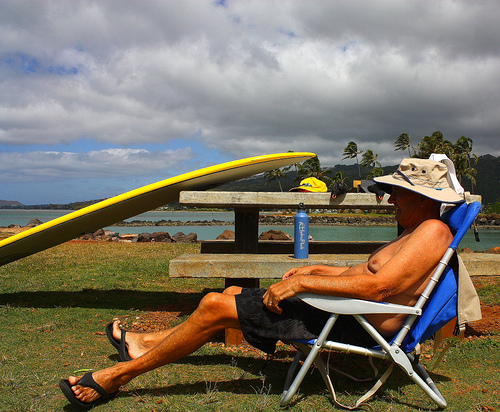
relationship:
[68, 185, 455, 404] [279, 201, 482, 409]
man relaxing in lawn chair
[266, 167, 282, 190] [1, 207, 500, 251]
palm tree on other side of river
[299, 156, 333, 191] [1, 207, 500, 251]
palm tree on other side of river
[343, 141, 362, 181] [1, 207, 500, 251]
palm tree on other side of river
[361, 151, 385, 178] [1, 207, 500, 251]
palm tree on other side of river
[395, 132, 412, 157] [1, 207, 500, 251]
palm tree on other side of river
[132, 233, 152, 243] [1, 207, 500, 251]
rock on bank of river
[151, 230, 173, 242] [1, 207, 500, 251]
rock on bank of river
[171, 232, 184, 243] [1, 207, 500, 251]
rock on bank of river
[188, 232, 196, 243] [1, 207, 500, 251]
rock on bank of river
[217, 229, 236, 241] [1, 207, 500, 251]
rock on bank of river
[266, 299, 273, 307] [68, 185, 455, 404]
wedding ring of man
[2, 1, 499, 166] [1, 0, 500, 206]
clouds in sky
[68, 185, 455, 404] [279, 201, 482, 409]
man sitting in lawn chair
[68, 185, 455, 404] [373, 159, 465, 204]
man with hat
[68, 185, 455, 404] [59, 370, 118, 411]
man wearing flip flop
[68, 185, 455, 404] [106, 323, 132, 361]
man wearing flip flop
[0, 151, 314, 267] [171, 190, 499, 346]
surfboard sitting on picnic table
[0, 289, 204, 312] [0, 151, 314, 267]
shadow of surfboard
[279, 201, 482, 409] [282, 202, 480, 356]
lawn chair with lining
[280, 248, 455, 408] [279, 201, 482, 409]
metal on lawn chair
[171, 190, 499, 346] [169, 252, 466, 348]
picnic table with bench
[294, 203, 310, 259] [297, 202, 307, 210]
water bottle with cap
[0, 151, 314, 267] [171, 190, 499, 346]
surfboard leaning on picnic table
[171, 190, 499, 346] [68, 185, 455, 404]
picnic table next to man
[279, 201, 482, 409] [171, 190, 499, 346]
lawn chair next to picnic table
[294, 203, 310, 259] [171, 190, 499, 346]
water bottle sitting on picnic table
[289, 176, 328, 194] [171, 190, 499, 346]
baseball cap sitting on picnic table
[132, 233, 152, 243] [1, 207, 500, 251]
rock next to river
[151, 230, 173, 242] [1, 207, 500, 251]
rock next to river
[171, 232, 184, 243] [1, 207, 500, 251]
rock next to river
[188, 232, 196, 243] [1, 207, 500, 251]
rock next to river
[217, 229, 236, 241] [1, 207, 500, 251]
rock next to river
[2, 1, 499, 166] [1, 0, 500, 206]
clouds floating in sky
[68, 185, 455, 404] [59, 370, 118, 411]
man wears flip flop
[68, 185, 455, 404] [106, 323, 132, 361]
man wears flip flop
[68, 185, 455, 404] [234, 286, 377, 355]
man wears shorts